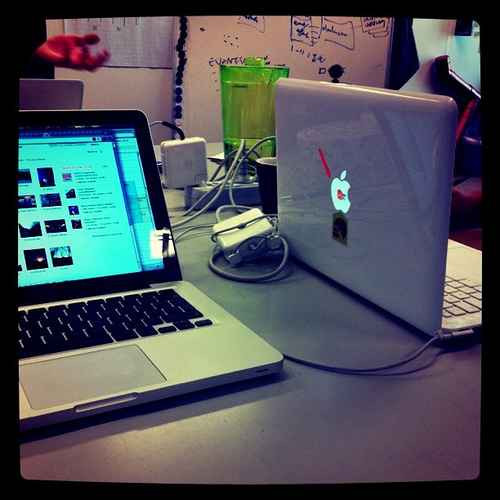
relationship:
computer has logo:
[258, 63, 477, 359] [322, 165, 354, 218]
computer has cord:
[258, 63, 477, 359] [201, 204, 292, 293]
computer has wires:
[258, 63, 477, 359] [177, 125, 275, 228]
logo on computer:
[322, 165, 354, 218] [258, 63, 477, 359]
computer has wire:
[258, 63, 477, 359] [285, 328, 442, 383]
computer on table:
[258, 63, 477, 359] [32, 262, 478, 476]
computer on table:
[23, 95, 286, 447] [32, 262, 478, 476]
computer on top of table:
[258, 63, 477, 359] [32, 262, 478, 476]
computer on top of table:
[23, 95, 286, 447] [32, 262, 478, 476]